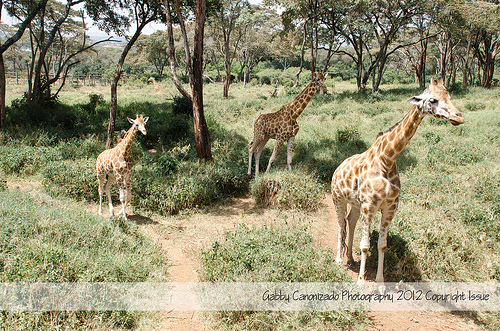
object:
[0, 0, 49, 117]
tree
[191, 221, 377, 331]
shrub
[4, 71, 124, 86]
gate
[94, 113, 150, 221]
giraffe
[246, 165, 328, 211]
bushes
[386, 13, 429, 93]
trees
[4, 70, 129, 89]
fence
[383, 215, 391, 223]
spot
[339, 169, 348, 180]
spot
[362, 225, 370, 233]
spot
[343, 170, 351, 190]
spot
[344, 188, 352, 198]
spot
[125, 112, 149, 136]
head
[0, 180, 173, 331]
shrubs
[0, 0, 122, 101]
tree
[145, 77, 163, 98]
giraffe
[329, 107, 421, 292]
body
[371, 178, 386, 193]
orange marking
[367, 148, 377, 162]
orange marking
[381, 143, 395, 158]
orange marking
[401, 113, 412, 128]
orange marking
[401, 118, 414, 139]
orange marking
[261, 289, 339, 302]
name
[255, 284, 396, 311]
company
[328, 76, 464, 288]
giraffe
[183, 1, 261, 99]
tree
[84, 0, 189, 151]
tree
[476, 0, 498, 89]
tree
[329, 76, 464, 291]
giraffe's walking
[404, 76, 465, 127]
head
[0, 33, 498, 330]
grassy area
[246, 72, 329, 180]
giraffe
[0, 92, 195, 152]
shadow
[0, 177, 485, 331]
way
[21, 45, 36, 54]
shed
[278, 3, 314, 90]
trees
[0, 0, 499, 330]
sun